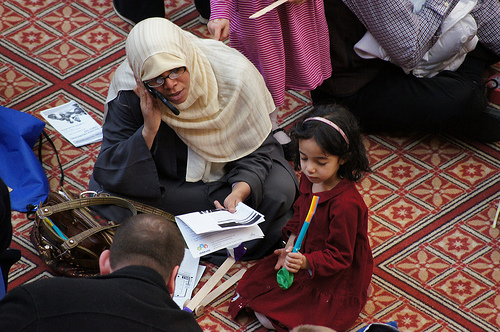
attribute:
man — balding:
[0, 206, 195, 327]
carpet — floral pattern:
[0, 0, 500, 329]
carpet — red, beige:
[372, 169, 462, 314]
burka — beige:
[113, 10, 270, 150]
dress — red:
[230, 177, 373, 325]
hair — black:
[287, 105, 367, 180]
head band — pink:
[301, 113, 350, 141]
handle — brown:
[45, 184, 142, 257]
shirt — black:
[7, 262, 194, 330]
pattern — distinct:
[7, 7, 497, 331]